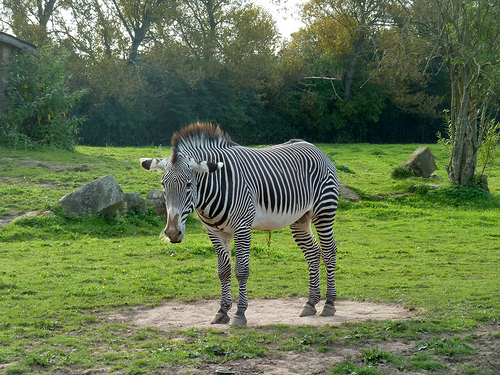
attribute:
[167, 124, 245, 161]
main — spiny, black, brown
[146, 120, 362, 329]
zebra — black, white, standing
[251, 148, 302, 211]
stripes — black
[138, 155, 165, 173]
ear — pointy, pointed, white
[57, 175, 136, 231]
stone — large, angular, grey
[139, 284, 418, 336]
dirt — circular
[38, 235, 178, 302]
grass — green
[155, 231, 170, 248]
whiskers — white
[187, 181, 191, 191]
eye — black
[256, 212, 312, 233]
belly — white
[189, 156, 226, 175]
ear — pointed, white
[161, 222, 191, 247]
nose — brown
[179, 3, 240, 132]
tree — green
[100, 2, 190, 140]
tree — green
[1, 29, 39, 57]
roof — grey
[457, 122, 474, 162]
bark — grey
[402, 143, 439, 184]
rock — angular